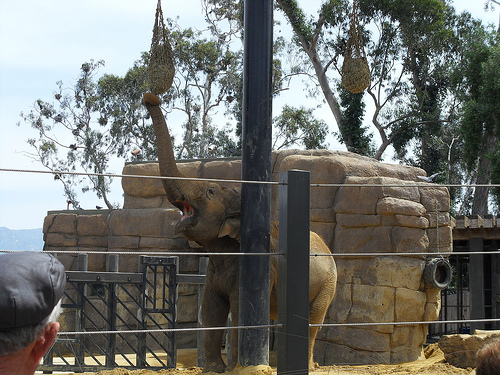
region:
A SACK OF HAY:
[332, 0, 383, 110]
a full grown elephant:
[137, 82, 344, 367]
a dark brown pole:
[267, 161, 322, 369]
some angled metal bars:
[71, 291, 173, 367]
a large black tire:
[411, 248, 470, 302]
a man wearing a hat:
[0, 242, 100, 367]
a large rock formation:
[27, 120, 461, 365]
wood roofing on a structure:
[434, 197, 498, 330]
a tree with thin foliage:
[20, 52, 306, 225]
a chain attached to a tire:
[421, 187, 459, 299]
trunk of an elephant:
[111, 98, 201, 173]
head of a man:
[0, 246, 111, 366]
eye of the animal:
[190, 178, 225, 217]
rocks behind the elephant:
[358, 177, 424, 274]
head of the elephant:
[136, 144, 246, 275]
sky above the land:
[12, 169, 49, 216]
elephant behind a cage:
[130, 119, 255, 279]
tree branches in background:
[372, 67, 450, 144]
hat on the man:
[19, 239, 72, 289]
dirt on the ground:
[359, 351, 399, 373]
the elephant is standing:
[96, 89, 348, 345]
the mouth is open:
[147, 189, 217, 238]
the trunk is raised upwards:
[112, 75, 209, 237]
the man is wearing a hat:
[0, 237, 80, 362]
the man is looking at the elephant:
[1, 242, 77, 361]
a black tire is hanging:
[414, 190, 462, 302]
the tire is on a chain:
[412, 187, 457, 286]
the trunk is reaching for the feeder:
[129, 10, 189, 135]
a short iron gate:
[52, 239, 190, 362]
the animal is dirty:
[122, 130, 339, 367]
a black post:
[214, 47, 349, 354]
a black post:
[175, 90, 282, 335]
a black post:
[178, 37, 322, 274]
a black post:
[225, 150, 325, 350]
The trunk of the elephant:
[137, 93, 195, 188]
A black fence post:
[280, 163, 314, 373]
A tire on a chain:
[424, 255, 456, 290]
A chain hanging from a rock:
[431, 205, 447, 262]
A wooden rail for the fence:
[71, 267, 143, 287]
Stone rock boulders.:
[339, 150, 405, 355]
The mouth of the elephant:
[162, 190, 201, 227]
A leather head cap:
[0, 242, 69, 332]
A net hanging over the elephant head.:
[141, 4, 189, 100]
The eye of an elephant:
[204, 185, 218, 199]